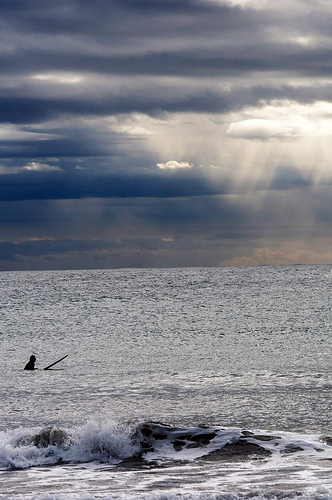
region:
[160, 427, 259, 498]
the water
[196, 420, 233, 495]
the water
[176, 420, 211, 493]
the water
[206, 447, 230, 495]
the water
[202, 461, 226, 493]
the water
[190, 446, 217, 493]
the water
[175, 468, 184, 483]
the water is dark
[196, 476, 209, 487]
the water is dark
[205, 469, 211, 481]
the water is dark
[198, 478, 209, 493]
the water is dark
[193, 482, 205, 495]
the water is dark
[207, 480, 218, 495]
the water is dark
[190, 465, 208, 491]
the water is dark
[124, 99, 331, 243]
the sun rays shining through the clouds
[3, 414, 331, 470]
the wave in the water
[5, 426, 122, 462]
the white foam from the wave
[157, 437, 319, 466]
the white foam in the water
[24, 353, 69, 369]
the surfer in the water with their board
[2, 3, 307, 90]
the gray clouds in the sky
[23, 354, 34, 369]
the person in the water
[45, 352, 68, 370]
the board sticking out of the water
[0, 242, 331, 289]
the horizon of the ocean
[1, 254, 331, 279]
where the sky and ocean meet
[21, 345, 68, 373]
person is on surf board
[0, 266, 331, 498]
water is dark and wavy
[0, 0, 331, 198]
dark clouds block the sun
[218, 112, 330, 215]
rays of sunlight between clouds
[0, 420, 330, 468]
wave in the ocean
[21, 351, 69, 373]
surfboarder is silhouetted in water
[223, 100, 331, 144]
white clouds among the dark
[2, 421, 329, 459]
white surf on wave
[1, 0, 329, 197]
storm clouds in sky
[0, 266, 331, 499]
ocean is dark blue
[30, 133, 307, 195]
The sky is cloudy.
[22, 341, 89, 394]
The man is in the water.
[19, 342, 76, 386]
He is sitting on his surfboard.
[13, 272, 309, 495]
The water has many waves.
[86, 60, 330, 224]
The sun is shining through the clouds.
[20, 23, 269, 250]
The clouds are dark.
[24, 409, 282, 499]
The waves are crashing on the shore.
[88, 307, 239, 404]
The water is blue.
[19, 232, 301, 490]
He is in the ocean.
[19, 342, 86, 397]
He is sitting.